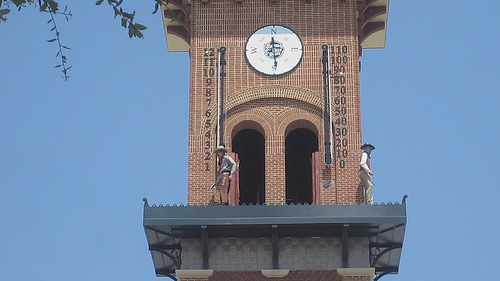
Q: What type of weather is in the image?
A: It is clear.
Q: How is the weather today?
A: It is clear.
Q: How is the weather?
A: It is clear.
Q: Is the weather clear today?
A: Yes, it is clear.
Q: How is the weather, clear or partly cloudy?
A: It is clear.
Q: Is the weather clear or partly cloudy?
A: It is clear.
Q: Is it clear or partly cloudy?
A: It is clear.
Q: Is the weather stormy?
A: No, it is clear.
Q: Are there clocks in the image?
A: Yes, there is a clock.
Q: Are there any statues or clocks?
A: Yes, there is a clock.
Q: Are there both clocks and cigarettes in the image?
A: No, there is a clock but no cigarettes.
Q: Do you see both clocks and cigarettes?
A: No, there is a clock but no cigarettes.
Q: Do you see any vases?
A: No, there are no vases.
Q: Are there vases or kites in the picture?
A: No, there are no vases or kites.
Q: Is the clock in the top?
A: Yes, the clock is in the top of the image.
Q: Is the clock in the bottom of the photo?
A: No, the clock is in the top of the image.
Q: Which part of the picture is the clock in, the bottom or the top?
A: The clock is in the top of the image.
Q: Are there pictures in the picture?
A: No, there are no pictures.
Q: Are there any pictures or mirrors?
A: No, there are no pictures or mirrors.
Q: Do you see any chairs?
A: No, there are no chairs.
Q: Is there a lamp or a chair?
A: No, there are no chairs or lamps.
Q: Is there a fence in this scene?
A: No, there are no fences.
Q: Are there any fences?
A: No, there are no fences.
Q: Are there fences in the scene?
A: No, there are no fences.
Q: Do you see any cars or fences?
A: No, there are no fences or cars.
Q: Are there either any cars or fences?
A: No, there are no fences or cars.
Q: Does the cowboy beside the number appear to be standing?
A: Yes, the cowboy is standing.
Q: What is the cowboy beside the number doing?
A: The cowboy is standing.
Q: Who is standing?
A: The cowboy is standing.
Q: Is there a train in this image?
A: No, there are no trains.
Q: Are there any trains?
A: No, there are no trains.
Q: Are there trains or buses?
A: No, there are no trains or buses.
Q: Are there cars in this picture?
A: No, there are no cars.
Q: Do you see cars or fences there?
A: No, there are no cars or fences.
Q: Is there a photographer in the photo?
A: No, there are no photographers.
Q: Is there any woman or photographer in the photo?
A: No, there are no photographers or women.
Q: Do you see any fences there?
A: No, there are no fences.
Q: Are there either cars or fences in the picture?
A: No, there are no fences or cars.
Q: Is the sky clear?
A: Yes, the sky is clear.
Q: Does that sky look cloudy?
A: No, the sky is clear.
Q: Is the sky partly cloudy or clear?
A: The sky is clear.